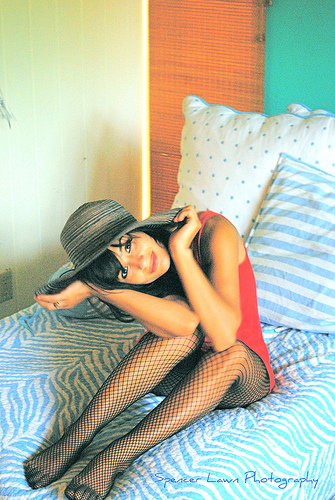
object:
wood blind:
[219, 0, 265, 5]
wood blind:
[148, 5, 264, 17]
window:
[148, 0, 263, 215]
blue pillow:
[240, 152, 333, 341]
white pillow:
[168, 92, 334, 200]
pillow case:
[173, 167, 268, 195]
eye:
[117, 264, 130, 278]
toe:
[65, 480, 77, 498]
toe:
[73, 484, 83, 498]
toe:
[81, 488, 90, 499]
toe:
[87, 491, 95, 498]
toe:
[96, 495, 102, 498]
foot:
[63, 450, 127, 498]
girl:
[22, 198, 276, 499]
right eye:
[118, 263, 131, 282]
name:
[154, 468, 239, 486]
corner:
[114, 2, 176, 227]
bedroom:
[1, 1, 332, 496]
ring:
[52, 300, 63, 312]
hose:
[160, 367, 207, 428]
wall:
[129, 11, 307, 215]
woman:
[23, 207, 284, 498]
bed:
[0, 185, 333, 498]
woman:
[84, 225, 174, 291]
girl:
[35, 213, 246, 318]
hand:
[24, 273, 142, 335]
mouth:
[140, 233, 167, 297]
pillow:
[245, 153, 334, 337]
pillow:
[174, 92, 261, 238]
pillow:
[287, 100, 320, 114]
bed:
[113, 400, 334, 498]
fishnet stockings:
[21, 316, 271, 498]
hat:
[27, 186, 208, 309]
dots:
[223, 157, 241, 183]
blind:
[149, 0, 264, 219]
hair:
[72, 229, 196, 324]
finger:
[33, 295, 66, 310]